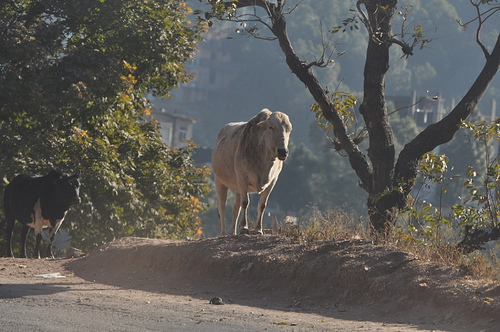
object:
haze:
[160, 1, 483, 113]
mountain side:
[157, 22, 489, 234]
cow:
[211, 108, 298, 234]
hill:
[0, 0, 499, 242]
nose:
[276, 144, 289, 165]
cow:
[204, 105, 300, 239]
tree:
[239, 3, 496, 244]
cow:
[213, 106, 291, 245]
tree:
[229, 0, 498, 238]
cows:
[2, 101, 302, 261]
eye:
[264, 122, 276, 133]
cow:
[206, 105, 296, 234]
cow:
[6, 156, 88, 256]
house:
[154, 110, 197, 149]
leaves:
[3, 101, 136, 165]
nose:
[277, 147, 290, 161]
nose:
[71, 194, 82, 203]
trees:
[0, 2, 489, 223]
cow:
[192, 107, 296, 241]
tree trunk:
[354, 171, 420, 243]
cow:
[185, 105, 314, 250]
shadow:
[3, 280, 53, 299]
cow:
[3, 167, 101, 269]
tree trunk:
[363, 10, 404, 245]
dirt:
[33, 259, 117, 323]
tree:
[1, 2, 203, 248]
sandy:
[0, 250, 499, 331]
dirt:
[175, 239, 273, 302]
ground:
[0, 240, 499, 329]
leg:
[251, 188, 270, 235]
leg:
[237, 188, 251, 234]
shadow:
[5, 274, 58, 295]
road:
[1, 252, 498, 329]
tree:
[267, 3, 496, 241]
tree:
[257, 4, 497, 262]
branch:
[397, 41, 498, 184]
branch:
[353, 7, 399, 176]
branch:
[244, 6, 371, 179]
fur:
[221, 140, 267, 178]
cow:
[183, 90, 310, 256]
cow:
[3, 165, 84, 259]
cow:
[207, 102, 299, 249]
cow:
[3, 167, 87, 267]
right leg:
[237, 184, 253, 235]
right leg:
[26, 223, 46, 260]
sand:
[0, 285, 382, 330]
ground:
[0, 262, 499, 326]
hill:
[183, 1, 498, 234]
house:
[385, 89, 471, 133]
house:
[145, 106, 195, 170]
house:
[166, 0, 250, 109]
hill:
[0, 0, 499, 220]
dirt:
[0, 245, 493, 329]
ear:
[253, 117, 268, 129]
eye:
[285, 124, 293, 134]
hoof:
[252, 227, 263, 236]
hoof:
[240, 226, 252, 237]